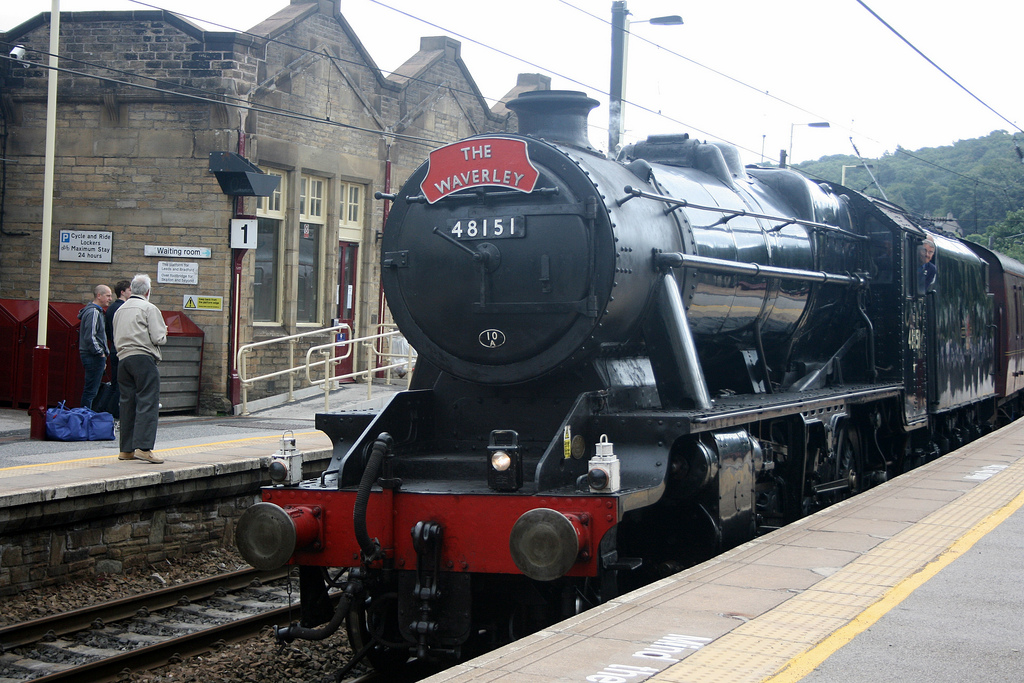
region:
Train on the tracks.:
[245, 46, 863, 628]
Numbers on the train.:
[325, 163, 652, 318]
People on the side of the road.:
[68, 201, 290, 462]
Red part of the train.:
[243, 437, 781, 671]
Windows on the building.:
[130, 77, 523, 410]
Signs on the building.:
[10, 156, 255, 337]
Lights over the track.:
[563, 0, 865, 212]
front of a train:
[380, 134, 609, 387]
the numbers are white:
[454, 221, 518, 238]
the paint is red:
[260, 482, 616, 578]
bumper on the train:
[510, 507, 578, 583]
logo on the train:
[482, 330, 503, 346]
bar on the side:
[629, 180, 864, 238]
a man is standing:
[114, 276, 169, 469]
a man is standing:
[84, 284, 111, 403]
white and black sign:
[231, 217, 258, 252]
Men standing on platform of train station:
[32, 255, 201, 484]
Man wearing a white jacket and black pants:
[100, 266, 183, 466]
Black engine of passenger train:
[239, 80, 898, 651]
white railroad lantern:
[577, 426, 638, 513]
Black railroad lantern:
[480, 420, 537, 503]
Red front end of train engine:
[234, 465, 630, 621]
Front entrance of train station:
[192, 3, 427, 431]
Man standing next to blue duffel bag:
[37, 269, 118, 463]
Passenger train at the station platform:
[397, 77, 1021, 583]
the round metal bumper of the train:
[234, 499, 304, 573]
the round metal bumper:
[510, 507, 578, 583]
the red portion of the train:
[256, 483, 617, 581]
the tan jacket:
[109, 297, 170, 367]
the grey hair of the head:
[128, 272, 152, 298]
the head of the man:
[128, 270, 155, 300]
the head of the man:
[93, 281, 114, 304]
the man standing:
[84, 281, 116, 415]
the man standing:
[115, 272, 177, 460]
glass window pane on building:
[248, 220, 271, 323]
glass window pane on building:
[291, 220, 317, 320]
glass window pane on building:
[291, 191, 304, 214]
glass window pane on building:
[308, 194, 321, 218]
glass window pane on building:
[310, 178, 320, 195]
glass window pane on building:
[346, 201, 353, 218]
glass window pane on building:
[348, 182, 358, 199]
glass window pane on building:
[298, 197, 302, 208]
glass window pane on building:
[333, 194, 346, 217]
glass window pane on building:
[251, 189, 264, 209]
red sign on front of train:
[412, 138, 559, 205]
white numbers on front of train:
[440, 196, 527, 247]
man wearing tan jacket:
[99, 256, 198, 456]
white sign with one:
[217, 211, 269, 256]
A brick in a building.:
[75, 155, 105, 168]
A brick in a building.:
[51, 155, 75, 165]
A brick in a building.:
[53, 275, 88, 286]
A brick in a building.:
[145, 109, 166, 120]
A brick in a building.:
[182, 58, 212, 68]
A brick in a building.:
[113, 39, 136, 53]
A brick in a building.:
[211, 332, 230, 343]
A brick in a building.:
[108, 188, 146, 201]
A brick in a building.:
[258, 354, 277, 364]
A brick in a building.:
[133, 49, 156, 59]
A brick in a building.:
[189, 52, 212, 59]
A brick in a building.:
[208, 51, 225, 62]